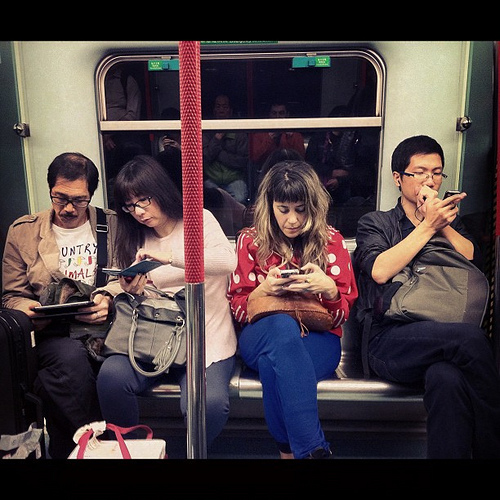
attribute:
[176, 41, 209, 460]
pole — silver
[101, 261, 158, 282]
book — small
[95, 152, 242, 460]
woman — Asian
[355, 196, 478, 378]
jacket — black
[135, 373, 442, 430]
seat — metallic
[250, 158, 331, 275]
hair — long, blonde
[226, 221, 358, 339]
shirt — red, white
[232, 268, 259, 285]
dots — polka dots, white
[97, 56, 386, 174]
window — tinted 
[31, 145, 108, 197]
hair — short, dark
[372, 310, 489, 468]
pants — blue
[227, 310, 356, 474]
pants — blue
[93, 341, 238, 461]
pants — blue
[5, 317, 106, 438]
pants — blue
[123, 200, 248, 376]
sweater — knitted, long sleeved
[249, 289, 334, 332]
handbag — gray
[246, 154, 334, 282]
hair — long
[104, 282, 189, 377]
handbag — black, grey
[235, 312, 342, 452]
jeans — blue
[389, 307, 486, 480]
pants — dark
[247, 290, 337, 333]
bag — brown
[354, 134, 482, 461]
man — Asian 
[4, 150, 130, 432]
man — Asian , balding 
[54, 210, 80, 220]
mustache — dark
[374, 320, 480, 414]
jeans — blue